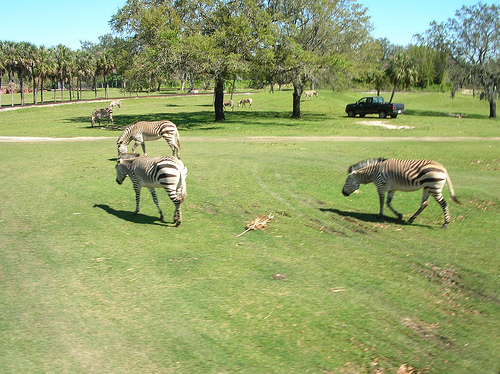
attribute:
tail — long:
[441, 167, 458, 206]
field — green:
[6, 244, 190, 370]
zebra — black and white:
[325, 149, 468, 234]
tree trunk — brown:
[287, 77, 310, 125]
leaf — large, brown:
[230, 210, 289, 258]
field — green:
[7, 95, 489, 364]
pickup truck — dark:
[345, 92, 407, 122]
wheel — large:
[378, 110, 388, 117]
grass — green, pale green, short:
[2, 81, 499, 370]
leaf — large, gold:
[235, 210, 273, 237]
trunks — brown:
[197, 86, 319, 128]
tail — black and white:
[441, 165, 461, 205]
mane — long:
[348, 155, 388, 173]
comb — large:
[343, 156, 382, 172]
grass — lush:
[212, 118, 326, 131]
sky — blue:
[4, 4, 97, 36]